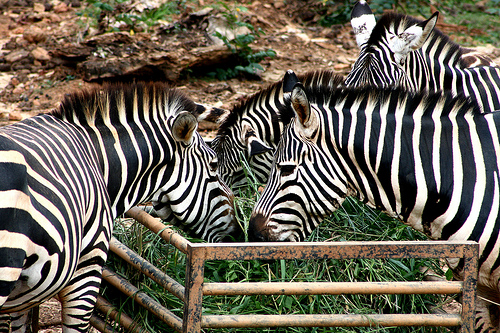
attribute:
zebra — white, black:
[0, 72, 240, 326]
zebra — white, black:
[208, 77, 484, 290]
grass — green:
[134, 198, 450, 328]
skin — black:
[402, 108, 412, 181]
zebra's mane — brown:
[71, 84, 178, 106]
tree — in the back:
[88, 4, 271, 76]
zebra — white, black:
[237, 55, 496, 283]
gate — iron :
[156, 205, 488, 330]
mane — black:
[299, 85, 476, 117]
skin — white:
[432, 115, 446, 193]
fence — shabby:
[103, 205, 485, 327]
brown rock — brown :
[52, 27, 246, 72]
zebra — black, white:
[357, 37, 427, 122]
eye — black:
[272, 155, 304, 178]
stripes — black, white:
[338, 91, 355, 157]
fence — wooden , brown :
[173, 236, 482, 331]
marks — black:
[463, 274, 478, 306]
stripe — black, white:
[340, 96, 368, 208]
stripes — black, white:
[331, 114, 498, 210]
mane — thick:
[53, 80, 165, 130]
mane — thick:
[396, 8, 459, 63]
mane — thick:
[335, 84, 469, 121]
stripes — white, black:
[82, 125, 153, 161]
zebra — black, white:
[251, 102, 498, 244]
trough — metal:
[112, 194, 478, 331]